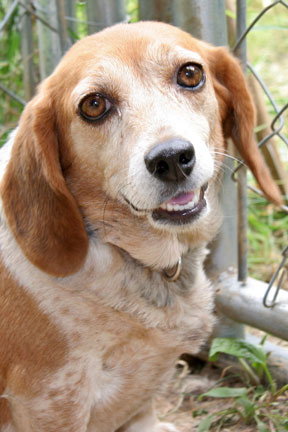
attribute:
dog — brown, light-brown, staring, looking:
[1, 21, 285, 431]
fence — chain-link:
[205, 2, 287, 388]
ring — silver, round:
[164, 254, 188, 284]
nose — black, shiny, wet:
[143, 141, 196, 183]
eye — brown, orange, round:
[81, 95, 112, 117]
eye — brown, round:
[178, 64, 205, 90]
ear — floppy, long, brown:
[210, 45, 284, 208]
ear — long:
[1, 89, 90, 278]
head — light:
[1, 16, 282, 275]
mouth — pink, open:
[156, 186, 205, 213]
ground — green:
[157, 355, 286, 431]